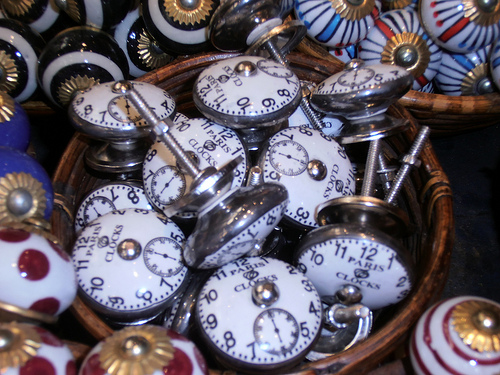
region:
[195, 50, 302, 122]
small clock decor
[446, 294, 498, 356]
brass top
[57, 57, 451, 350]
basket full of clock screws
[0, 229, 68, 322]
red and white pok a dots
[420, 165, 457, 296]
brown wicker basket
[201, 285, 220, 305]
small black number 10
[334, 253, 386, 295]
Paris Clocks logo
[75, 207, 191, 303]
miniature black and white clock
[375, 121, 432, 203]
metal screw and bolt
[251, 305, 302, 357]
small clock inside a clock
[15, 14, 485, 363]
decorative drawer knobs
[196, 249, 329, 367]
drawer know with a clock design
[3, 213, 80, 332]
drawer know with a red polka dot design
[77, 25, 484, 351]
drawer knobs displayed in small brown baskets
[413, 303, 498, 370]
drawer know with red sripes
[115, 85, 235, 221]
screw on back of drawer knob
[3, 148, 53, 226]
blue drawer knob with gold accents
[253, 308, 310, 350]
clock on the clock drawer knob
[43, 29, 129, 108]
black drawer knob with white stripe and gold accents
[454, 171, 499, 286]
black table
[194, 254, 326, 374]
A clock in the edge of the bowl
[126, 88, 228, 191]
The screw on the end of the car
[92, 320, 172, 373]
The top of the ball is gold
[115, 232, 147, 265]
The middle of the clock is silver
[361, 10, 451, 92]
The ball is orange and white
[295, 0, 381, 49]
The ball has blue, orange, and white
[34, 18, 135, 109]
The ball is black and white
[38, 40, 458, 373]
The bowl is made of wicker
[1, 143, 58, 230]
The ball is the color blue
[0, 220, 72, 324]
The ball is the color of white and wine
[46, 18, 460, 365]
bunch of cock button/cufflinks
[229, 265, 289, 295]
the words "paris clocks" and a logo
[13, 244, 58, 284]
red sparkling polka dot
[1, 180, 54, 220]
gold ornamental topper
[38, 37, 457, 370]
brown wicker basket holding clock items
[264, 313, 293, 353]
clock hands that read six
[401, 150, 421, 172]
silver screw on bolt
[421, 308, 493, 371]
red stripes around a white ball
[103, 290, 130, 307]
a distorted number nine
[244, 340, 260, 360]
the number seven in black font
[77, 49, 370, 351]
white faces of clock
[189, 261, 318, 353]
clocks have black numbers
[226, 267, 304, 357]
clocks have black hands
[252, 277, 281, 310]
metal ball in center of clocks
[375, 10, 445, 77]
white and red items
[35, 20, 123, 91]
black and white items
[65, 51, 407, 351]
clocks in center of batch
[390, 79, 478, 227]
brown striped baskets hold clocks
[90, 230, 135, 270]
black company name on clocks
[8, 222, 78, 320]
red and white polka-dot items